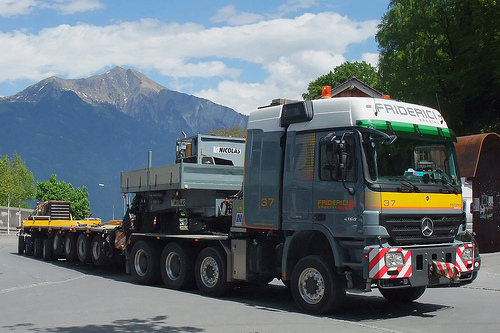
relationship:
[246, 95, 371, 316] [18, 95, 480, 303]
side angle of truck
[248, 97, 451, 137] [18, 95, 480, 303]
top of truck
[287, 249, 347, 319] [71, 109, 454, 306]
wheel on a truck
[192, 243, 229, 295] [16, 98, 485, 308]
wheel on a truck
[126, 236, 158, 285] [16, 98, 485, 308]
wheel on a truck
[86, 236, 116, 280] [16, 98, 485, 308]
wheel on a truck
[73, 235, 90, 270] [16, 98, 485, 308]
wheel on a truck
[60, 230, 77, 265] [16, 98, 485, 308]
wheel on a truck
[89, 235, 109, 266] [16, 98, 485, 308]
wheel on a truck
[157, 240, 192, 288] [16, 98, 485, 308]
wheel on a truck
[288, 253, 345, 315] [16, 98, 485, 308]
wheel on a truck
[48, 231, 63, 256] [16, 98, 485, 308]
wheel on a truck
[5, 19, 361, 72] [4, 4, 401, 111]
white clouds in blue sky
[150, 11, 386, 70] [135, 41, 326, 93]
clouds in sky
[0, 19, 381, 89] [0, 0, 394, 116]
clouds in sky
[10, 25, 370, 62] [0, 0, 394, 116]
clouds in sky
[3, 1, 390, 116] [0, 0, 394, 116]
clouds in sky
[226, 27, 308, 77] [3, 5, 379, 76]
clouds in sky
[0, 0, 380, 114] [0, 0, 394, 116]
clouds in sky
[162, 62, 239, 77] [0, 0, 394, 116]
clouds in sky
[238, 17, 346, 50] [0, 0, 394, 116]
clouds in sky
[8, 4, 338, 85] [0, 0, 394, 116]
clouds in sky